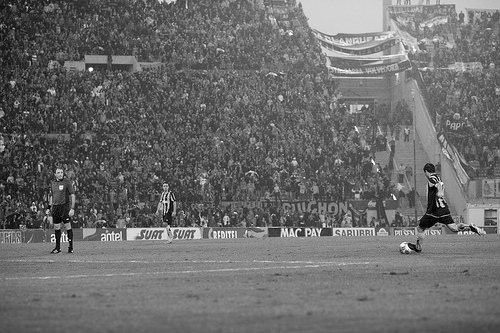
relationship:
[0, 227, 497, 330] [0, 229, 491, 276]
soccer pitch has section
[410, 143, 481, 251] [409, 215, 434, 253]
soccer player has leg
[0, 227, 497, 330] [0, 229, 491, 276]
soccer pitch has part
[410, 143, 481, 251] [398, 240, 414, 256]
soccer player going to hit ball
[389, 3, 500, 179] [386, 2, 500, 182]
spectators are in section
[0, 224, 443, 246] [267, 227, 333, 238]
advertising board has section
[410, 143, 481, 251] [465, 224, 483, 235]
soccer player has foot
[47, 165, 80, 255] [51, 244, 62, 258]
referee has foot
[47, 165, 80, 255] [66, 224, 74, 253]
referee has leg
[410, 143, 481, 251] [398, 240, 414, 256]
soccer player about to kick ball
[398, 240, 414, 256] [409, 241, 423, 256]
ball near foot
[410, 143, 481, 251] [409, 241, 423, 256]
soccer player has foot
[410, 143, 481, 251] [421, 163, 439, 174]
soccer player has hair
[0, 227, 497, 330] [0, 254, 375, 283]
soccer pitch has lines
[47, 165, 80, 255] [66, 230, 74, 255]
referee wearing sock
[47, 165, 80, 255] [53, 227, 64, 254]
referee wearing sock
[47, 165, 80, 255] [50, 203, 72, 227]
referee wearing shorts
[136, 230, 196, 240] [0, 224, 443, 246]
writting on advertising board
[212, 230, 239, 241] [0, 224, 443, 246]
writting on advertising board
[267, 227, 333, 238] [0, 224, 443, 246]
writting on advertising board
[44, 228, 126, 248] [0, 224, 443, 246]
writting on advertising board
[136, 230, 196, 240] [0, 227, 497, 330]
writting around soccer pitch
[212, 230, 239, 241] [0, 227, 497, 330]
writting around soccer pitch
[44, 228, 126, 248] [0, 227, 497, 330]
writting around soccer pitch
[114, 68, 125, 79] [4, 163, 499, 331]
people in soccer game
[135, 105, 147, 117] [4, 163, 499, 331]
people in soccer game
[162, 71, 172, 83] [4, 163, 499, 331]
people in soccer game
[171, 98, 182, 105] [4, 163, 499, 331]
people in soccer game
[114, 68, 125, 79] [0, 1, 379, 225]
people in stands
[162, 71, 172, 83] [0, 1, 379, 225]
people in stands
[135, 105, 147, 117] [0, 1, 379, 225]
people in stands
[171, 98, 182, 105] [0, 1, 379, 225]
people in stands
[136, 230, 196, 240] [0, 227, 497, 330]
writting across soccer pitch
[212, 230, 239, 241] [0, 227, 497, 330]
writting across soccer pitch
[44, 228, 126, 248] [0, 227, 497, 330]
writting across soccer pitch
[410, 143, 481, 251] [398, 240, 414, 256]
soccer player kicking a ball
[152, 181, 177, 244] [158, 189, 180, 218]
person wearing shirt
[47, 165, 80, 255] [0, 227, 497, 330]
referee standing in soccer pitch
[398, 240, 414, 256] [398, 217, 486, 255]
ball about to be kicked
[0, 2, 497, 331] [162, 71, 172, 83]
stadium full of people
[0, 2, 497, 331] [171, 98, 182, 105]
stadium full of people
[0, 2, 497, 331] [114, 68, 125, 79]
stadium full of people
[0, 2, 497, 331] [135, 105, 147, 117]
stadium full of people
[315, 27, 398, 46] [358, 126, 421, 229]
banner over stairwell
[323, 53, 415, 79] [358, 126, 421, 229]
banner over stairwell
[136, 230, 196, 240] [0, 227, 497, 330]
writting along soccer pitch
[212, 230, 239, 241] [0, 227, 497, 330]
writting along soccer pitch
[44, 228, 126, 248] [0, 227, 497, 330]
writting along soccer pitch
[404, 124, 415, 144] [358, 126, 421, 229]
people in stairwell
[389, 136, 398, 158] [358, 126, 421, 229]
people in stairwell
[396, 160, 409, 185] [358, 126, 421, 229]
people in stairwell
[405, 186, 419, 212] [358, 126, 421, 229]
people in stairwell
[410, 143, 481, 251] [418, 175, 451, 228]
soccer player wearing uniform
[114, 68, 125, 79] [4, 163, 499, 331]
people washing soccer game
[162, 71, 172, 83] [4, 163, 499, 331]
people washing soccer game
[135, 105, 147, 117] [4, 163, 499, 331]
people washing soccer game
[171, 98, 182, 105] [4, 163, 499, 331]
people washing soccer game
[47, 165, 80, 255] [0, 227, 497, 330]
referee in soccer pitch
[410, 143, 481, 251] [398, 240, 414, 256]
soccer player kicking ball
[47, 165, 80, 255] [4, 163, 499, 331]
referee watching soccer game